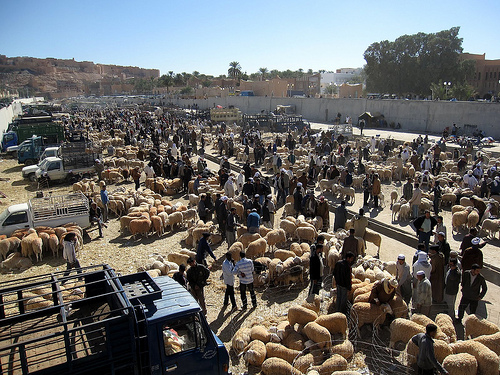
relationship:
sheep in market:
[114, 191, 196, 249] [52, 67, 412, 345]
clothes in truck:
[165, 334, 184, 350] [1, 272, 227, 374]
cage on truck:
[30, 197, 93, 212] [1, 180, 85, 236]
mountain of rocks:
[2, 49, 66, 95] [15, 55, 38, 69]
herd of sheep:
[246, 293, 357, 372] [254, 322, 279, 360]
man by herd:
[192, 227, 219, 268] [235, 222, 320, 270]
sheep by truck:
[3, 222, 80, 266] [1, 180, 85, 236]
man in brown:
[341, 238, 362, 262] [348, 237, 355, 254]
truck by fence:
[19, 137, 81, 159] [0, 105, 19, 187]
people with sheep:
[282, 127, 367, 193] [369, 153, 402, 180]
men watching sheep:
[394, 246, 452, 309] [362, 284, 457, 351]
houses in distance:
[164, 76, 365, 96] [4, 39, 491, 90]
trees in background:
[230, 58, 294, 83] [199, 13, 391, 118]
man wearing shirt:
[192, 227, 219, 268] [411, 280, 433, 308]